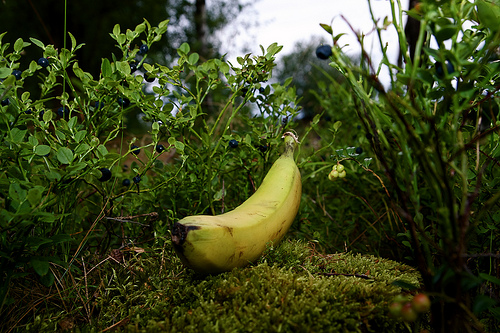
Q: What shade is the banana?
A: Yellow.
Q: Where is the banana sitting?
A: On the grass.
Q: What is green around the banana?
A: Blueberry bushes.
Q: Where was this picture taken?
A: Outside in the wild.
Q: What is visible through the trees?
A: The sky.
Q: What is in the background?
A: Trees.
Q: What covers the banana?
A: A peel.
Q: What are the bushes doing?
A: Holding the banana.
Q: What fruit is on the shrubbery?
A: Banana.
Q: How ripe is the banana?
A: Almost ripe with some green.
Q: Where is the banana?
A: On the shrubs.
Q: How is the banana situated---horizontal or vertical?
A: Horizontal.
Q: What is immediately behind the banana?
A: A shrub.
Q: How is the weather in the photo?
A: Fair.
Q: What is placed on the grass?
A: Banana.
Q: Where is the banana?
A: On the ground.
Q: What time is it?
A: Afternoon.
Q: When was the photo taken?
A: During the daytime.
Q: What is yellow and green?
A: Banana.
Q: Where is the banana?
A: On the ground.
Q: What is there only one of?
A: A banana.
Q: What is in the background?
A: The sky.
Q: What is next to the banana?
A: Grass.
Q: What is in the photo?
A: A banana.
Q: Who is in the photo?
A: No people.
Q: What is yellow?
A: The banana.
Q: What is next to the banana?
A: Leaves.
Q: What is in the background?
A: The sky.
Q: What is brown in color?
A: End of the banana.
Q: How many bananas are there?
A: One.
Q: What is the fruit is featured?
A: A banana.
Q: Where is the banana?
A: A garden.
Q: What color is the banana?
A: Yellow.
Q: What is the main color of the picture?
A: Green.